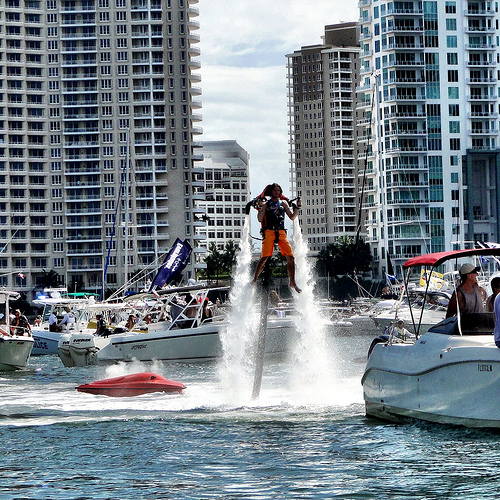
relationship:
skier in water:
[241, 181, 319, 297] [2, 344, 500, 498]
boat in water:
[347, 251, 500, 441] [2, 344, 500, 498]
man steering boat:
[442, 262, 490, 322] [347, 251, 500, 441]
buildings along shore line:
[0, 3, 500, 299] [4, 284, 500, 329]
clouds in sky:
[195, 18, 286, 132] [190, 1, 370, 243]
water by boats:
[2, 344, 500, 498] [1, 260, 500, 418]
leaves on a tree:
[340, 241, 376, 269] [331, 235, 376, 284]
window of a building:
[394, 65, 418, 79] [371, 6, 492, 279]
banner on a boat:
[148, 240, 188, 291] [113, 293, 171, 334]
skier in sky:
[241, 181, 319, 297] [190, 1, 370, 243]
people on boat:
[444, 262, 500, 347] [347, 251, 500, 441]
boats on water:
[1, 260, 500, 418] [2, 344, 500, 498]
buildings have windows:
[0, 3, 500, 299] [8, 3, 483, 274]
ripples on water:
[17, 426, 499, 497] [2, 344, 500, 498]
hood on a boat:
[395, 247, 500, 268] [347, 251, 500, 441]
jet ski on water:
[75, 362, 178, 402] [2, 344, 500, 498]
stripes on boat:
[108, 323, 287, 360] [79, 290, 300, 363]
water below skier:
[2, 344, 500, 498] [241, 181, 319, 297]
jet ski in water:
[75, 362, 178, 402] [2, 344, 500, 498]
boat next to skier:
[347, 251, 500, 441] [241, 181, 319, 297]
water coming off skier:
[221, 215, 348, 402] [241, 181, 319, 297]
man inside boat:
[442, 262, 490, 322] [347, 251, 500, 441]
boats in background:
[1, 260, 500, 418] [1, 223, 498, 370]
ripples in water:
[17, 426, 499, 497] [2, 344, 500, 498]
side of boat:
[357, 343, 499, 427] [347, 251, 500, 441]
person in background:
[13, 309, 32, 333] [1, 223, 498, 370]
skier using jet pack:
[241, 181, 319, 297] [242, 199, 302, 236]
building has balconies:
[371, 6, 492, 279] [380, 13, 492, 249]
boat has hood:
[347, 251, 500, 441] [395, 247, 500, 268]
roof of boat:
[40, 290, 86, 300] [25, 293, 88, 355]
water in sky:
[221, 215, 348, 402] [190, 1, 370, 243]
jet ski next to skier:
[75, 362, 178, 402] [241, 181, 319, 297]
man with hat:
[442, 262, 490, 322] [460, 263, 475, 277]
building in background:
[371, 6, 492, 279] [1, 223, 498, 370]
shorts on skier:
[260, 221, 292, 256] [241, 181, 319, 297]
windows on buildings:
[8, 3, 483, 274] [0, 3, 500, 299]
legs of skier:
[253, 253, 303, 288] [241, 181, 319, 297]